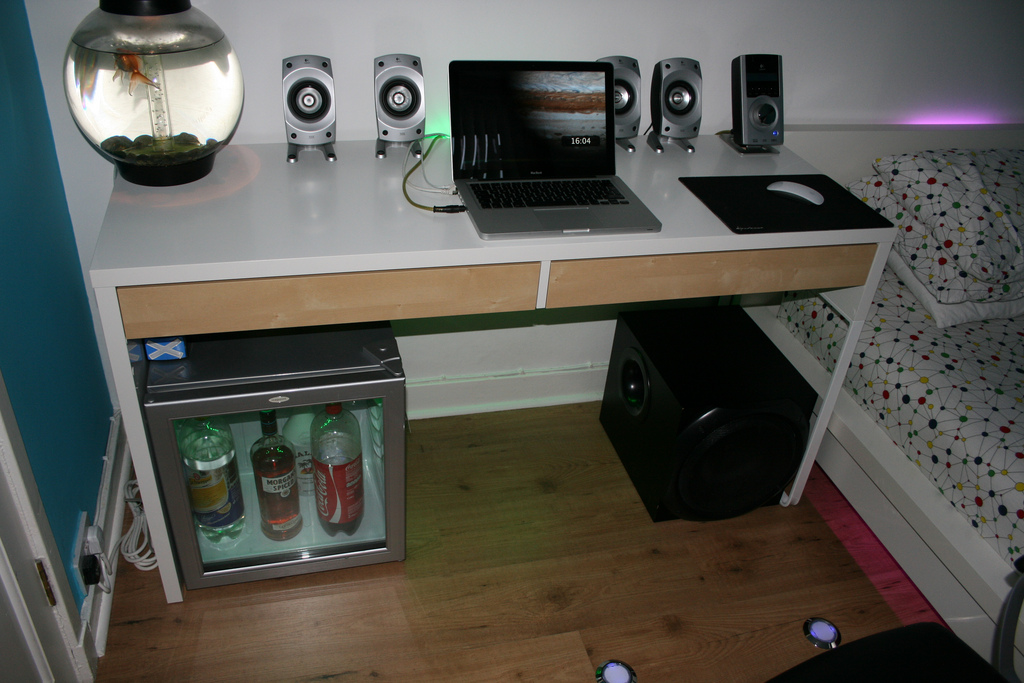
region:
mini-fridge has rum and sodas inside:
[144, 355, 410, 589]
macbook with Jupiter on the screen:
[445, 58, 671, 237]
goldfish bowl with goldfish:
[57, 0, 245, 187]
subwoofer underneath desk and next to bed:
[600, 307, 815, 523]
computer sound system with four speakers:
[280, 52, 792, 163]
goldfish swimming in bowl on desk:
[63, 2, 241, 187]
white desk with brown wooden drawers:
[91, 132, 901, 603]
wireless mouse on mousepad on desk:
[679, 175, 901, 233]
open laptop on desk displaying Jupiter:
[446, 56, 665, 243]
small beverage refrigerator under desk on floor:
[142, 321, 406, 588]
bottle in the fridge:
[285, 413, 346, 434]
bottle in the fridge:
[256, 432, 296, 549]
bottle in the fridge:
[188, 442, 252, 542]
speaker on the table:
[285, 56, 330, 167]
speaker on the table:
[375, 38, 421, 149]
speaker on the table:
[595, 38, 638, 143]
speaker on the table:
[659, 51, 718, 150]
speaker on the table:
[724, 48, 792, 148]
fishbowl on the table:
[39, 41, 223, 201]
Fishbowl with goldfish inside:
[33, 0, 278, 187]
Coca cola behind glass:
[301, 386, 384, 549]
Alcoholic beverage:
[247, 395, 312, 547]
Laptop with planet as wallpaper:
[433, 51, 639, 252]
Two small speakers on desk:
[272, 16, 432, 206]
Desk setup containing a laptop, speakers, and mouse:
[279, 19, 891, 270]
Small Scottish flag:
[125, 326, 195, 372]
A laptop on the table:
[444, 55, 661, 234]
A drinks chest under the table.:
[148, 327, 412, 597]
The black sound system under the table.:
[599, 298, 818, 521]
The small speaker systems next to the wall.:
[280, 39, 780, 154]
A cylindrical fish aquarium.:
[59, 0, 243, 188]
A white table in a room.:
[95, 130, 899, 605]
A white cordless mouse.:
[765, 182, 823, 205]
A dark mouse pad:
[681, 169, 894, 231]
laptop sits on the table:
[436, 53, 671, 231]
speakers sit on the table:
[280, 37, 432, 168]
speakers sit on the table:
[594, 46, 711, 160]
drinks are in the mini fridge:
[132, 330, 423, 606]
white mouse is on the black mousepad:
[680, 154, 896, 243]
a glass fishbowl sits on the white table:
[47, 4, 289, 202]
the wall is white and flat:
[424, 13, 861, 52]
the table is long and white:
[82, 181, 901, 575]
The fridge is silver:
[109, 309, 448, 617]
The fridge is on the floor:
[112, 313, 430, 595]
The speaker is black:
[582, 263, 842, 552]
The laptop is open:
[431, 38, 673, 274]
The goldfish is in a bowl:
[49, 4, 256, 197]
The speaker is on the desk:
[260, 50, 344, 172]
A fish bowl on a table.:
[65, 0, 247, 182]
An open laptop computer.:
[445, 57, 667, 241]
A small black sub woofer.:
[600, 297, 819, 523]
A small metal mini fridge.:
[132, 311, 407, 588]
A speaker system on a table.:
[277, 45, 429, 163]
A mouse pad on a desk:
[669, 169, 892, 236]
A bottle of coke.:
[309, 396, 366, 536]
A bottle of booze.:
[245, 414, 309, 538]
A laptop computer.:
[440, 56, 662, 250]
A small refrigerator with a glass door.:
[140, 345, 413, 596]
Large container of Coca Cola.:
[308, 395, 366, 536]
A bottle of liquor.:
[245, 410, 306, 543]